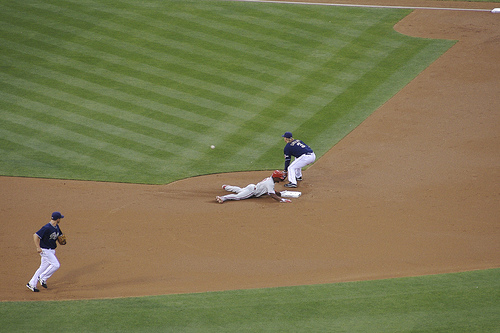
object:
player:
[212, 166, 292, 206]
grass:
[2, 0, 457, 184]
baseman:
[280, 130, 317, 188]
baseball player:
[212, 165, 296, 208]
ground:
[0, 0, 499, 332]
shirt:
[34, 221, 62, 249]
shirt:
[286, 141, 312, 157]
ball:
[210, 143, 215, 148]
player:
[280, 130, 317, 187]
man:
[214, 170, 291, 204]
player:
[25, 210, 65, 292]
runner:
[214, 168, 294, 208]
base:
[490, 2, 499, 13]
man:
[20, 207, 70, 294]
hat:
[52, 211, 64, 219]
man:
[269, 127, 326, 198]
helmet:
[267, 169, 284, 181]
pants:
[22, 249, 58, 291]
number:
[294, 138, 306, 149]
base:
[280, 186, 301, 202]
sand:
[334, 165, 423, 217]